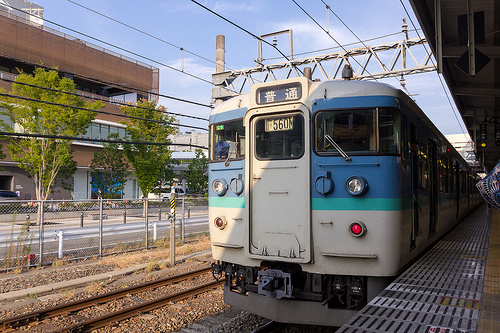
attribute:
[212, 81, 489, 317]
train — blue, green, white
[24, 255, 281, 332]
tracks — metal, black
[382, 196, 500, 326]
platform — metal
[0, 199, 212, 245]
fence — metal, chain link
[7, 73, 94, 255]
tree — green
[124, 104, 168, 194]
tree — short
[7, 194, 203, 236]
street — paved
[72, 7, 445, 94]
sky — cloudy, blue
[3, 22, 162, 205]
building — brown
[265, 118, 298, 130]
number — black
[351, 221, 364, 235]
light — red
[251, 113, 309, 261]
door — white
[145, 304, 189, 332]
rocks — brown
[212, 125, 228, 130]
window sticker — green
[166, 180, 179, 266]
post — yellow, black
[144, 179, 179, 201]
van — white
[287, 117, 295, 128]
letter — black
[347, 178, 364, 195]
light — silver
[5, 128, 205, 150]
cables — black